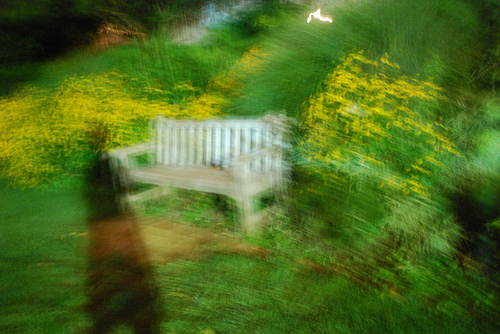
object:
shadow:
[80, 119, 168, 334]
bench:
[105, 110, 287, 238]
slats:
[155, 120, 271, 172]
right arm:
[232, 148, 279, 186]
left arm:
[105, 141, 156, 172]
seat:
[126, 162, 247, 195]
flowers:
[0, 64, 225, 183]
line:
[307, 8, 332, 24]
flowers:
[305, 46, 459, 196]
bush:
[286, 48, 473, 270]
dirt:
[90, 216, 261, 265]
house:
[165, 0, 269, 50]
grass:
[111, 0, 500, 109]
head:
[83, 127, 117, 149]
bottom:
[79, 145, 175, 334]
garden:
[0, 0, 499, 333]